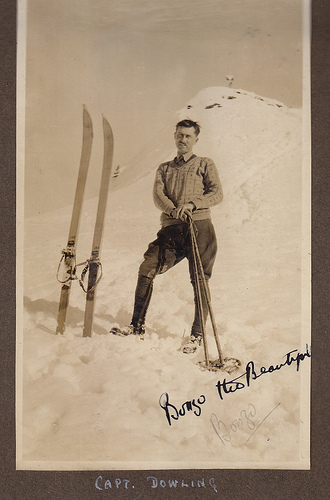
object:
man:
[110, 118, 224, 353]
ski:
[83, 113, 114, 337]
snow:
[22, 85, 301, 460]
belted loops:
[78, 261, 103, 293]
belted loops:
[56, 249, 77, 284]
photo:
[15, 0, 311, 472]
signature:
[158, 392, 205, 427]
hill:
[23, 85, 300, 462]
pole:
[188, 218, 210, 366]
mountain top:
[165, 85, 302, 178]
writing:
[146, 475, 218, 491]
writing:
[215, 343, 310, 400]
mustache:
[178, 138, 186, 146]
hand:
[172, 203, 194, 219]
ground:
[22, 85, 302, 462]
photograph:
[0, 0, 329, 498]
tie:
[177, 157, 184, 165]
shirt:
[176, 151, 194, 163]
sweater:
[153, 155, 225, 228]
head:
[174, 118, 200, 153]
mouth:
[177, 140, 187, 146]